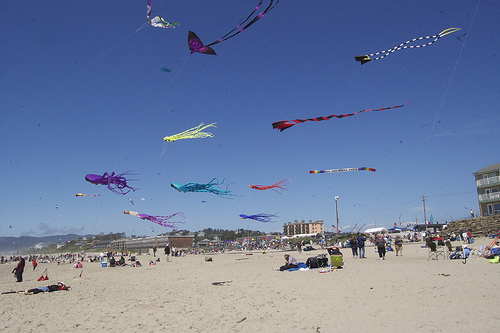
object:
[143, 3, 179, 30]
kite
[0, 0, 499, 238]
sky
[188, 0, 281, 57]
kite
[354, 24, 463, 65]
kite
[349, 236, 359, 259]
people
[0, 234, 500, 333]
sand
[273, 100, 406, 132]
kite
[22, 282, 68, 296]
person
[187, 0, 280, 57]
butterfly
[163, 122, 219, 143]
kite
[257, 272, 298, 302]
tan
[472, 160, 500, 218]
house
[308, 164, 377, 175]
banner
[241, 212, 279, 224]
kite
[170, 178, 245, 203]
kite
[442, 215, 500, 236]
wall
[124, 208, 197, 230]
kites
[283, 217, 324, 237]
building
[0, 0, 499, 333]
background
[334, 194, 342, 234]
pole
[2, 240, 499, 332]
beach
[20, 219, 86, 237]
clouds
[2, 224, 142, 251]
distance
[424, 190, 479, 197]
power line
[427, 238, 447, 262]
chair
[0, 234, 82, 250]
mountain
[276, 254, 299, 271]
body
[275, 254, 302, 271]
man